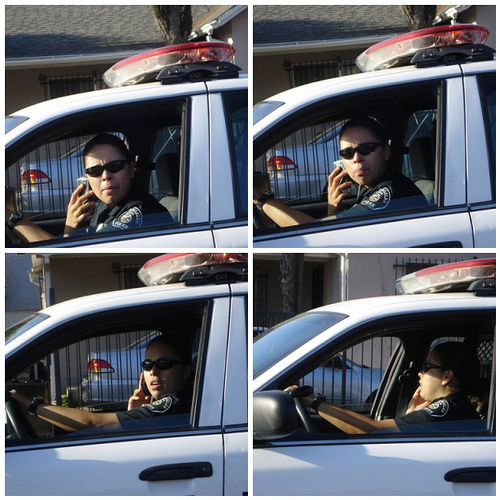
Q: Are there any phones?
A: Yes, there is a phone.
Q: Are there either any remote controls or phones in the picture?
A: Yes, there is a phone.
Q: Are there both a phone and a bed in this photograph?
A: No, there is a phone but no beds.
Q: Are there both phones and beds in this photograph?
A: No, there is a phone but no beds.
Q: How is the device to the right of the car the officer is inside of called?
A: The device is a phone.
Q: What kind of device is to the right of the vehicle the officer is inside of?
A: The device is a phone.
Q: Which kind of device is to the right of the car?
A: The device is a phone.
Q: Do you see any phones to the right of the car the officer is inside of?
A: Yes, there is a phone to the right of the car.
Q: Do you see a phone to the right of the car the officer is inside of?
A: Yes, there is a phone to the right of the car.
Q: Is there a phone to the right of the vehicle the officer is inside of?
A: Yes, there is a phone to the right of the car.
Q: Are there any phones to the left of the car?
A: No, the phone is to the right of the car.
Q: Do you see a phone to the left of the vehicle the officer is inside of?
A: No, the phone is to the right of the car.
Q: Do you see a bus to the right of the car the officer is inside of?
A: No, there is a phone to the right of the car.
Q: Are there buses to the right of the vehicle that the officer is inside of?
A: No, there is a phone to the right of the car.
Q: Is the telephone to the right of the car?
A: Yes, the telephone is to the right of the car.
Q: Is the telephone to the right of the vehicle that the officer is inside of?
A: Yes, the telephone is to the right of the car.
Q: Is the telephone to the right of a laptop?
A: No, the telephone is to the right of the car.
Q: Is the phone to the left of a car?
A: No, the phone is to the right of a car.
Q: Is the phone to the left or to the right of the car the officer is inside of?
A: The phone is to the right of the car.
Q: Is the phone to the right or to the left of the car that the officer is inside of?
A: The phone is to the right of the car.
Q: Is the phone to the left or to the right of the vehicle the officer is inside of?
A: The phone is to the right of the car.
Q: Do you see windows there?
A: Yes, there is a window.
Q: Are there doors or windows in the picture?
A: Yes, there is a window.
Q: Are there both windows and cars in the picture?
A: Yes, there are both a window and a car.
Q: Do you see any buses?
A: No, there are no buses.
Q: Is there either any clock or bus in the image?
A: No, there are no buses or clocks.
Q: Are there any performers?
A: No, there are no performers.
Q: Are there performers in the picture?
A: No, there are no performers.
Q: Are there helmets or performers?
A: No, there are no performers or helmets.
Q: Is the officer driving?
A: Yes, the officer is driving.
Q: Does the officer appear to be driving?
A: Yes, the officer is driving.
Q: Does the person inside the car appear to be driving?
A: Yes, the officer is driving.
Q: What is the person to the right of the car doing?
A: The officer is driving.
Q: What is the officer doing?
A: The officer is driving.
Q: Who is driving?
A: The officer is driving.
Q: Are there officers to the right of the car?
A: Yes, there is an officer to the right of the car.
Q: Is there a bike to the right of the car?
A: No, there is an officer to the right of the car.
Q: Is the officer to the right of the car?
A: Yes, the officer is to the right of the car.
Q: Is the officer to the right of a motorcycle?
A: No, the officer is to the right of the car.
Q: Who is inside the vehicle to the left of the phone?
A: The officer is inside the car.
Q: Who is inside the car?
A: The officer is inside the car.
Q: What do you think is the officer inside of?
A: The officer is inside the car.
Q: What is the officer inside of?
A: The officer is inside the car.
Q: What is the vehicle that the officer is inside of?
A: The vehicle is a car.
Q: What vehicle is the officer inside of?
A: The officer is inside the car.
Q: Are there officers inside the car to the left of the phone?
A: Yes, there is an officer inside the car.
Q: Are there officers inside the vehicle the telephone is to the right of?
A: Yes, there is an officer inside the car.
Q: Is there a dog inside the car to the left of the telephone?
A: No, there is an officer inside the car.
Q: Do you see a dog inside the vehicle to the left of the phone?
A: No, there is an officer inside the car.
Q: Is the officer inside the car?
A: Yes, the officer is inside the car.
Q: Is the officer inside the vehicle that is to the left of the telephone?
A: Yes, the officer is inside the car.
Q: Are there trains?
A: No, there are no trains.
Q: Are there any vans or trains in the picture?
A: No, there are no trains or vans.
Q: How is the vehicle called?
A: The vehicle is a car.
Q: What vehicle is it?
A: The vehicle is a car.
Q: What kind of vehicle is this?
A: This is a car.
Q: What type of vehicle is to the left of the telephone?
A: The vehicle is a car.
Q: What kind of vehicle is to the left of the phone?
A: The vehicle is a car.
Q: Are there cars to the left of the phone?
A: Yes, there is a car to the left of the phone.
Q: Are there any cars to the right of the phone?
A: No, the car is to the left of the phone.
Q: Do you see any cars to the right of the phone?
A: No, the car is to the left of the phone.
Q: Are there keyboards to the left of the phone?
A: No, there is a car to the left of the phone.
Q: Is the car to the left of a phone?
A: Yes, the car is to the left of a phone.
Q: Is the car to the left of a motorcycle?
A: No, the car is to the left of a phone.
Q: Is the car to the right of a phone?
A: No, the car is to the left of a phone.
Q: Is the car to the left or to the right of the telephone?
A: The car is to the left of the telephone.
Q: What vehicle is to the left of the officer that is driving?
A: The vehicle is a car.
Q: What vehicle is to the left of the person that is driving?
A: The vehicle is a car.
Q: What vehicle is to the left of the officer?
A: The vehicle is a car.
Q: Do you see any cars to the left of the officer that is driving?
A: Yes, there is a car to the left of the officer.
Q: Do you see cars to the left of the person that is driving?
A: Yes, there is a car to the left of the officer.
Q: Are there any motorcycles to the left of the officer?
A: No, there is a car to the left of the officer.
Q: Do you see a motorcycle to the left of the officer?
A: No, there is a car to the left of the officer.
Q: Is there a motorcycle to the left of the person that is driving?
A: No, there is a car to the left of the officer.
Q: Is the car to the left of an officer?
A: Yes, the car is to the left of an officer.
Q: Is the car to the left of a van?
A: No, the car is to the left of an officer.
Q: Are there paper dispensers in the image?
A: No, there are no paper dispensers.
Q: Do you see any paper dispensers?
A: No, there are no paper dispensers.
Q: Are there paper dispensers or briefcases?
A: No, there are no paper dispensers or briefcases.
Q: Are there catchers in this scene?
A: No, there are no catchers.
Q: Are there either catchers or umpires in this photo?
A: No, there are no catchers or umpires.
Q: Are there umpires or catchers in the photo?
A: No, there are no catchers or umpires.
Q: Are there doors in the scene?
A: Yes, there is a door.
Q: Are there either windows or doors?
A: Yes, there is a door.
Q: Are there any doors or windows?
A: Yes, there is a door.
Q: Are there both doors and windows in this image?
A: Yes, there are both a door and a window.